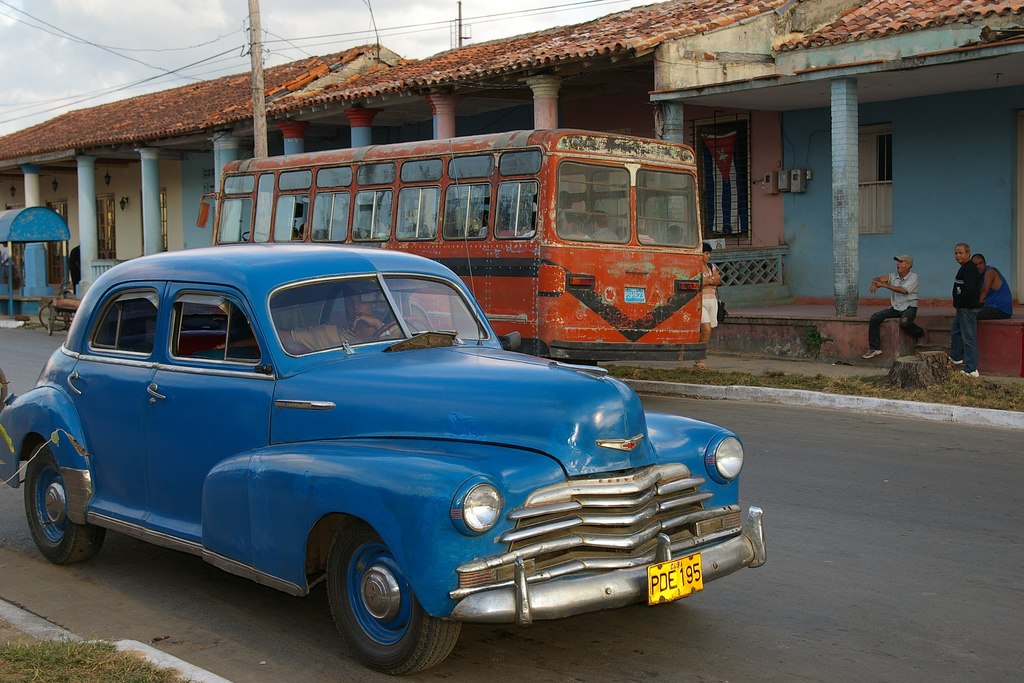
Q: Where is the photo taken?
A: On a street.